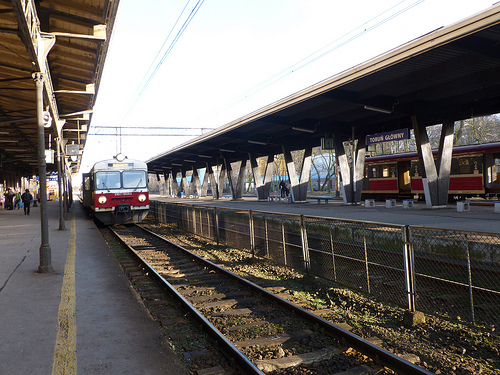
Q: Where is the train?
A: On the track.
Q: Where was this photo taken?
A: From a train platform.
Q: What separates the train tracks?
A: A chain link fence.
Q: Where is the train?
A: On the tracks.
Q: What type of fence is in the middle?
A: Chain link.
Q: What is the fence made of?
A: Metal.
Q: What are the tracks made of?
A: Metal.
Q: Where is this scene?
A: Train station.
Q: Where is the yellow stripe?
A: Platform.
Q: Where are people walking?
A: Platform.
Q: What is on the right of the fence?
A: Tracks.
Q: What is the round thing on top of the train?
A: Light.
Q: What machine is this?
A: A train.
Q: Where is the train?
A: On the tracks.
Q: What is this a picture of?
A: A train.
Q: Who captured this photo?
A: A photographer.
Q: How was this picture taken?
A: With a camera.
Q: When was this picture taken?
A: Daytime.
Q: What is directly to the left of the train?
A: A platform.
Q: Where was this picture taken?
A: At a train station.